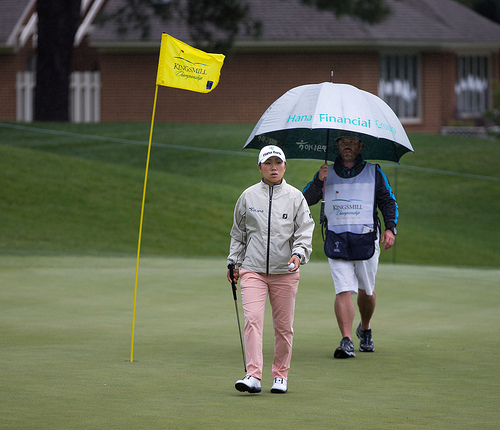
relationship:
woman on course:
[227, 145, 317, 394] [0, 121, 498, 427]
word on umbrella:
[285, 114, 370, 129] [242, 68, 413, 242]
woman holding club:
[227, 145, 317, 394] [224, 262, 248, 379]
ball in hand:
[289, 262, 294, 270] [287, 254, 302, 273]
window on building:
[379, 50, 423, 124] [0, 2, 499, 137]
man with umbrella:
[306, 134, 400, 361] [242, 68, 413, 242]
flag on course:
[127, 31, 229, 365] [0, 121, 498, 427]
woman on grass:
[227, 145, 317, 394] [211, 244, 213, 253]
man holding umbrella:
[306, 134, 400, 361] [242, 68, 413, 242]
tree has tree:
[33, 0, 84, 124] [33, 0, 84, 127]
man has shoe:
[306, 134, 400, 361] [335, 337, 355, 360]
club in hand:
[224, 262, 248, 379] [228, 267, 241, 283]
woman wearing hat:
[227, 145, 317, 394] [259, 144, 287, 168]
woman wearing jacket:
[227, 145, 317, 394] [228, 176, 317, 275]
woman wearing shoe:
[227, 145, 317, 394] [236, 373, 265, 397]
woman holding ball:
[227, 145, 317, 394] [289, 262, 294, 270]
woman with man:
[227, 145, 317, 394] [306, 134, 400, 361]